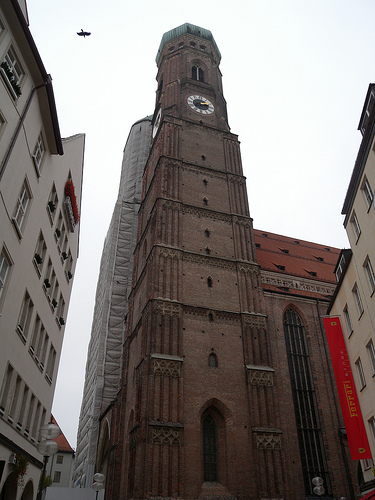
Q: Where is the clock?
A: On the tower.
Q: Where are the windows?
A: On the buildings.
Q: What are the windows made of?
A: Glass.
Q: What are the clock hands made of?
A: Metal.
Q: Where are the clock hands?
A: On the clock face.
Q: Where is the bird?
A: In the sky.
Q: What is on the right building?
A: A red banner.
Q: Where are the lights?
A: On lamp posts.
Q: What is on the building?
A: A clock.